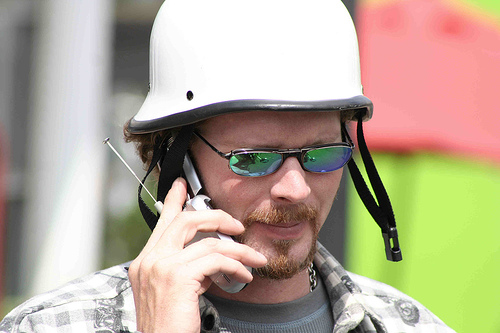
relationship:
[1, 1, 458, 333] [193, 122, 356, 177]
person has glasses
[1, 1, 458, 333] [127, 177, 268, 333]
person has a hand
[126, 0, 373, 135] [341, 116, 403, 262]
helmet has a strap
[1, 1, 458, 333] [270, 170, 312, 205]
person has a nose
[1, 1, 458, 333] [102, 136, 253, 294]
person has a phone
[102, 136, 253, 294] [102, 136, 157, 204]
phone has a antenna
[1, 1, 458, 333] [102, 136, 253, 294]
person holding phone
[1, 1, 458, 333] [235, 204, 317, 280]
person has facial hair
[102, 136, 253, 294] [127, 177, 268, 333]
phone in hand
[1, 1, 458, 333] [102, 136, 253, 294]
person talking on phone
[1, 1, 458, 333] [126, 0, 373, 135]
person wearing helmet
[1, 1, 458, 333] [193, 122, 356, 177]
person wearing glasses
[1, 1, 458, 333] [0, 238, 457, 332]
person wearing shirt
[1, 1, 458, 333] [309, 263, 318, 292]
person wearing chain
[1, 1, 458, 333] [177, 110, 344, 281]
person has a head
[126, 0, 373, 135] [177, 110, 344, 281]
helmet on top of head